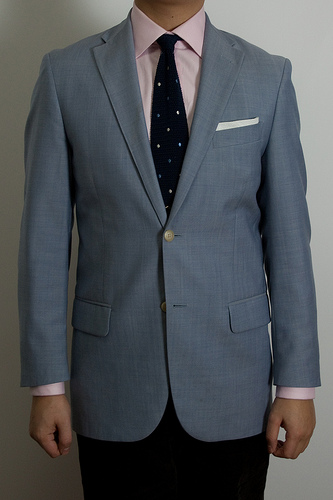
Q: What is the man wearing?
A: Suit.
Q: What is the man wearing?
A: Tie.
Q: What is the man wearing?
A: Black.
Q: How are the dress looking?
A: Formal.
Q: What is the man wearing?
A: Suit.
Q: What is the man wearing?
A: Tie.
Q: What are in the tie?
A: Dots.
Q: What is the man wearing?
A: Suit.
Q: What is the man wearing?
A: Suit.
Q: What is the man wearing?
A: Pant.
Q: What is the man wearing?
A: Tie.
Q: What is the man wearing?
A: Shirt.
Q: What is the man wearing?
A: Suit.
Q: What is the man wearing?
A: Pant.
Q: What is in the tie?
A: Dots.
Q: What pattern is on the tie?
A: Polka dots.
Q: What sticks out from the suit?
A: The man's pink shirt.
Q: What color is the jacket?
A: Grey.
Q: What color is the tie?
A: Black with polka dots.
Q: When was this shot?
A: Daytime.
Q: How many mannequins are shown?
A: 1.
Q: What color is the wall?
A: White.